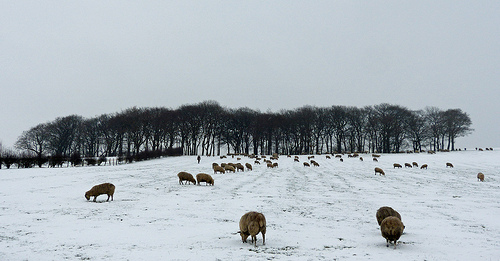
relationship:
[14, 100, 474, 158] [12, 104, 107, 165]
row of trees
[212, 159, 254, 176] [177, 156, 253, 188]
group of animals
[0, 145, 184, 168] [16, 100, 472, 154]
bushes near trees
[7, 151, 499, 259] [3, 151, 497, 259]
snow on ground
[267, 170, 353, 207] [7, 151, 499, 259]
prints in snow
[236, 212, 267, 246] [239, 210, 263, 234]
animal has fur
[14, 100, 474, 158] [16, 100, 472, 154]
range of trees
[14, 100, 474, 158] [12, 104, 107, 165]
forest of trees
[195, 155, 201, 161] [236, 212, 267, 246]
figure walking towards animal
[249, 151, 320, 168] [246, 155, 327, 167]
group of animals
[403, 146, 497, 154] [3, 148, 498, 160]
animals on horizon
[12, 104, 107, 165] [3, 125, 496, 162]
trees in distance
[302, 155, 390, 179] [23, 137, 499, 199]
sheep on a hill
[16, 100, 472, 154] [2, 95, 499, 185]
trees in background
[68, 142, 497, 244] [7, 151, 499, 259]
flock in snow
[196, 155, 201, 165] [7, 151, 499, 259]
person in snow